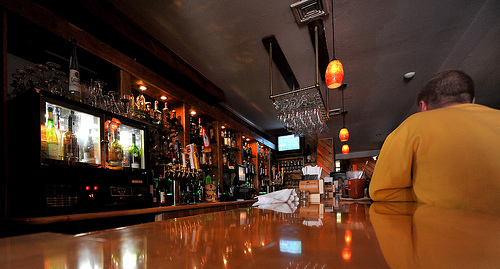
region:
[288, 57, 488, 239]
Man sitting at a bar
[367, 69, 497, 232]
Man wearing yellow shirt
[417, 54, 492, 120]
Man has short haircut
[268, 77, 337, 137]
Wine glasses hanging in rack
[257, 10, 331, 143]
Rack for wineglasses hanging from ceiling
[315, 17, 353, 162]
Lights hanging from ceiling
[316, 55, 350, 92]
Light is red and yellow in color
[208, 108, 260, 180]
Liquor bottles on shelf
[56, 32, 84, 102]
Tall glass bottle on shelf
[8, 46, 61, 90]
Stemmed glassware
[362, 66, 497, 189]
man wearing a sweat shirt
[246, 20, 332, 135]
glasses hanging from the ceiling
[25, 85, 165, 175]
top shelf liquor chilling out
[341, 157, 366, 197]
bloody mary drink with a straw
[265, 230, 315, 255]
TV reflection on the bar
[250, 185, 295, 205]
bar maid towel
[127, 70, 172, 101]
under shelf lighting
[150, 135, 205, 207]
beer taps for drafts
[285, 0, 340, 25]
ceiling ventilation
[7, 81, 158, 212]
refrigerator unit with lighting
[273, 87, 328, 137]
glasses of wine hanging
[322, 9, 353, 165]
yellow and orange lamps hanging in the roof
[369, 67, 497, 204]
man with yellow sweater sitting in a bar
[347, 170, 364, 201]
glass with pink coctel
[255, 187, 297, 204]
small white napkin in the bar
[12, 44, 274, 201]
bunch of alcohol bottles in bar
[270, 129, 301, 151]
small television at the top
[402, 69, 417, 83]
small ceiling light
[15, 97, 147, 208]
fridge to cool liquors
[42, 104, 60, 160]
green and yellow bottle in fridge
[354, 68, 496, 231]
person in yellow shirt sitting at the bar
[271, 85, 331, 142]
glasses hanging upside down in a rack from the ceiling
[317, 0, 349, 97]
yellow and orange lamp hanging from the ceiling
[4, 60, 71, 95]
glassed sitting upside down on top of a cooler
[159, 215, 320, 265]
shiny bar with reflections on it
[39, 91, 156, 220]
black cooler with bottles inside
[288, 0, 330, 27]
air conditioning vent in the ceiling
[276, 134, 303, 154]
TV up on the wall near the ceiling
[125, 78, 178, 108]
small recessed lighting fixtures over the shelves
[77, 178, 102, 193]
red lights on the black cooler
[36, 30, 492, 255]
bar with customer at counter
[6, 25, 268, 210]
shelves filled with liquor bottles and glasses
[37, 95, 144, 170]
lighted cabinet with green and brown bottles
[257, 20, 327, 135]
rows of glasses hanging from ceiling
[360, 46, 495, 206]
big man leaning elbow on counter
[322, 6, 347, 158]
row of yellow and orange hanging lights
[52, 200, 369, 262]
counter reflecting lights and television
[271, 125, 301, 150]
television in upper corner of bar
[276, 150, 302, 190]
additional shelving under television set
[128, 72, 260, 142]
round lights set above shelves